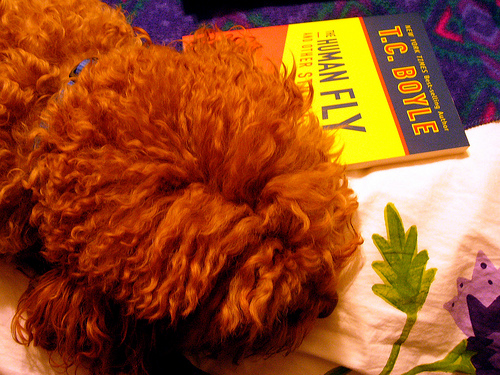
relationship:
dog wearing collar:
[0, 2, 364, 367] [70, 55, 95, 78]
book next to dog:
[183, 16, 470, 175] [0, 2, 364, 367]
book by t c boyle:
[183, 16, 470, 175] [377, 26, 440, 135]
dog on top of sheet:
[0, 2, 364, 367] [1, 120, 498, 373]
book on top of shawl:
[183, 16, 470, 175] [103, 0, 499, 131]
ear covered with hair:
[14, 269, 115, 372] [10, 274, 116, 373]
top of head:
[55, 57, 338, 286] [34, 34, 369, 348]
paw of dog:
[0, 208, 34, 252] [0, 2, 364, 367]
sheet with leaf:
[1, 120, 498, 373] [372, 202, 438, 373]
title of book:
[317, 32, 365, 134] [183, 16, 470, 175]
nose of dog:
[319, 291, 340, 316] [0, 2, 364, 367]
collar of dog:
[70, 55, 95, 78] [0, 2, 364, 367]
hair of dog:
[230, 24, 249, 36] [0, 2, 364, 367]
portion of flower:
[445, 252, 499, 336] [445, 252, 499, 336]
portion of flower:
[465, 294, 499, 374] [445, 252, 499, 336]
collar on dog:
[70, 55, 95, 78] [0, 2, 364, 367]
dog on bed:
[0, 2, 364, 367] [1, 1, 499, 373]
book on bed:
[183, 16, 470, 175] [1, 1, 499, 373]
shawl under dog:
[103, 0, 499, 131] [0, 2, 364, 367]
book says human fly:
[183, 16, 470, 175] [317, 39, 366, 134]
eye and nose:
[214, 260, 239, 287] [319, 291, 340, 316]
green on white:
[407, 337, 475, 374] [418, 333, 469, 366]